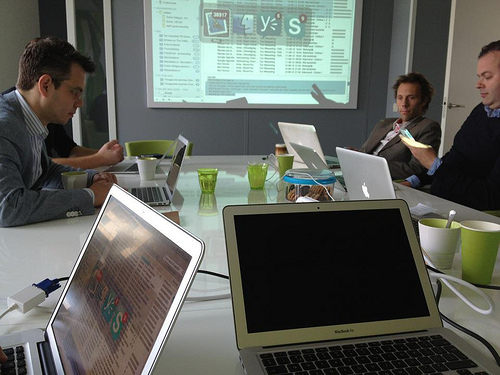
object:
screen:
[231, 206, 432, 334]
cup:
[195, 167, 216, 194]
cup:
[134, 156, 157, 180]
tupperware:
[283, 182, 346, 206]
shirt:
[15, 90, 51, 187]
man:
[0, 85, 124, 170]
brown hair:
[14, 36, 97, 92]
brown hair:
[391, 72, 435, 114]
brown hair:
[477, 39, 500, 60]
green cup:
[459, 220, 500, 287]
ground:
[0, 132, 500, 357]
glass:
[245, 161, 268, 189]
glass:
[416, 218, 461, 269]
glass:
[135, 156, 158, 181]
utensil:
[443, 208, 456, 228]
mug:
[277, 153, 295, 179]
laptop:
[220, 198, 500, 374]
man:
[0, 34, 117, 227]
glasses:
[57, 79, 87, 102]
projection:
[143, 0, 364, 110]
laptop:
[0, 183, 205, 375]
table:
[0, 153, 500, 375]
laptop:
[127, 133, 189, 207]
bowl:
[282, 167, 337, 204]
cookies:
[287, 184, 331, 201]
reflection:
[98, 202, 152, 259]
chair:
[125, 139, 192, 157]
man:
[343, 70, 443, 180]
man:
[399, 39, 500, 215]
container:
[283, 167, 336, 202]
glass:
[194, 167, 217, 193]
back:
[123, 139, 191, 157]